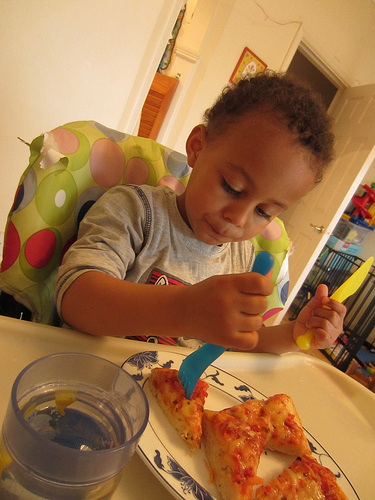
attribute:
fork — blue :
[177, 249, 285, 406]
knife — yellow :
[300, 256, 372, 352]